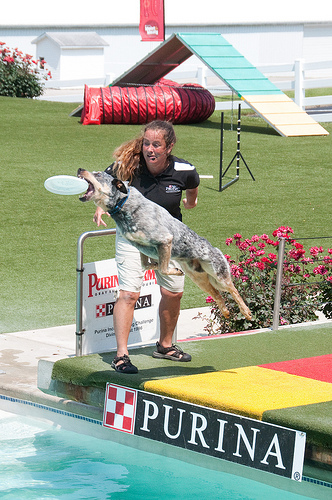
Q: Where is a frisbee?
A: In dog's mouth.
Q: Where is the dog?
A: In the air.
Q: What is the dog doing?
A: Catching a frisbee.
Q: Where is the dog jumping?
A: In the pool.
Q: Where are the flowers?
A: Next to the platform.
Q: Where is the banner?
A: Above the pool.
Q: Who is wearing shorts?
A: The women.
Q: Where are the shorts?
A: On the girl.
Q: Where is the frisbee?
A: Dogs mouth.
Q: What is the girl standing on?
A: A platform.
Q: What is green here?
A: Grass.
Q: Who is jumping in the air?
A: A dog.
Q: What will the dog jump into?
A: A pool.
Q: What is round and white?
A: Frisbee.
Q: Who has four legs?
A: The dog.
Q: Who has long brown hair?
A: The woman.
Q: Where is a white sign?
A: Behind the woman.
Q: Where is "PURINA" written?
A: Next to the pool.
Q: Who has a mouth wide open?
A: The dog.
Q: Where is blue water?
A: In pool.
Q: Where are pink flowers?
A: Behind a railing.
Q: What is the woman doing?
A: Coaching her dog.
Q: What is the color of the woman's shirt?
A: Black.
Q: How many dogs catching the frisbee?
A: One.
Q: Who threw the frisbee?
A: The woman.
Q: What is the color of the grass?
A: Green.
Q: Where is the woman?
A: Poolside.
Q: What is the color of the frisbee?
A: White.